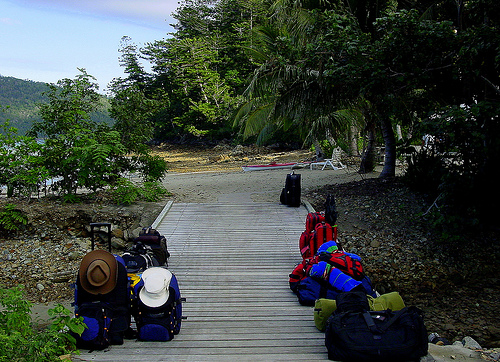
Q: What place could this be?
A: It is a sidewalk.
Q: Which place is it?
A: It is a sidewalk.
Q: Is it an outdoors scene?
A: Yes, it is outdoors.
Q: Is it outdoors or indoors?
A: It is outdoors.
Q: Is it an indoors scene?
A: No, it is outdoors.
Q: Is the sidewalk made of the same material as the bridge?
A: Yes, both the sidewalk and the bridge are made of wood.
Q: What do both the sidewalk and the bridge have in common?
A: The material, both the sidewalk and the bridge are wooden.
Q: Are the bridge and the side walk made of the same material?
A: Yes, both the bridge and the side walk are made of wood.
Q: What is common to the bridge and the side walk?
A: The material, both the bridge and the side walk are wooden.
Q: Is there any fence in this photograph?
A: No, there are no fences.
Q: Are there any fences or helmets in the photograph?
A: No, there are no fences or helmets.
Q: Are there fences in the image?
A: No, there are no fences.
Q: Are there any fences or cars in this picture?
A: No, there are no fences or cars.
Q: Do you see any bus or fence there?
A: No, there are no fences or buses.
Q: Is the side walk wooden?
A: Yes, the side walk is wooden.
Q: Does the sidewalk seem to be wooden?
A: Yes, the sidewalk is wooden.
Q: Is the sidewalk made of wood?
A: Yes, the sidewalk is made of wood.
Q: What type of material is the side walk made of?
A: The side walk is made of wood.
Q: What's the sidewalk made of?
A: The side walk is made of wood.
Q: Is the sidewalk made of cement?
A: No, the sidewalk is made of wood.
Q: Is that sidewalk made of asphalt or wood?
A: The sidewalk is made of wood.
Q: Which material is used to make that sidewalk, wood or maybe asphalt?
A: The sidewalk is made of wood.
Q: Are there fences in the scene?
A: No, there are no fences.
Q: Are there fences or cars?
A: No, there are no fences or cars.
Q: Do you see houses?
A: No, there are no houses.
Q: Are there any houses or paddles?
A: No, there are no houses or paddles.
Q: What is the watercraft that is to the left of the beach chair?
A: The watercraft is a canoe.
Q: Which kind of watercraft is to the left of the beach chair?
A: The watercraft is a canoe.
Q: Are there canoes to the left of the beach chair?
A: Yes, there is a canoe to the left of the beach chair.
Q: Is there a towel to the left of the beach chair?
A: No, there is a canoe to the left of the beach chair.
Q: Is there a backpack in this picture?
A: Yes, there is a backpack.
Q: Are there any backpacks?
A: Yes, there is a backpack.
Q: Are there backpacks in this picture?
A: Yes, there is a backpack.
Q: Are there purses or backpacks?
A: Yes, there is a backpack.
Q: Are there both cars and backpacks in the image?
A: No, there is a backpack but no cars.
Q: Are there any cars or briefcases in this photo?
A: No, there are no cars or briefcases.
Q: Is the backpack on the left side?
A: Yes, the backpack is on the left of the image.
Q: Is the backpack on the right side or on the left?
A: The backpack is on the left of the image.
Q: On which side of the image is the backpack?
A: The backpack is on the left of the image.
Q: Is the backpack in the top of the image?
A: No, the backpack is in the bottom of the image.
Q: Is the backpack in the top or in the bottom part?
A: The backpack is in the bottom of the image.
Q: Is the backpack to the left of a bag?
A: Yes, the backpack is to the left of a bag.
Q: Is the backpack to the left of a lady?
A: No, the backpack is to the left of a bag.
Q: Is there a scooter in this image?
A: No, there are no scooters.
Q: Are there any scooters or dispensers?
A: No, there are no scooters or dispensers.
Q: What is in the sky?
A: The clouds are in the sky.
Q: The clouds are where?
A: The clouds are in the sky.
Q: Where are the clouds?
A: The clouds are in the sky.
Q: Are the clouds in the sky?
A: Yes, the clouds are in the sky.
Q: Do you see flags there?
A: No, there are no flags.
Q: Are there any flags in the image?
A: No, there are no flags.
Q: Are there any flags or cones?
A: No, there are no flags or cones.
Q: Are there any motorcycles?
A: No, there are no motorcycles.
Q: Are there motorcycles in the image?
A: No, there are no motorcycles.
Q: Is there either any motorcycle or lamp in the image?
A: No, there are no motorcycles or lamps.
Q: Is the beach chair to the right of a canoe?
A: Yes, the beach chair is to the right of a canoe.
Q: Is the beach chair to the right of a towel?
A: No, the beach chair is to the right of a canoe.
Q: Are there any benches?
A: No, there are no benches.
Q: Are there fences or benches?
A: No, there are no benches or fences.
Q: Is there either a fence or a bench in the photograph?
A: No, there are no benches or fences.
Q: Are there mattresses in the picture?
A: No, there are no mattresses.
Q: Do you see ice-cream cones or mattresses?
A: No, there are no mattresses or ice-cream cones.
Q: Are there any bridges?
A: Yes, there is a bridge.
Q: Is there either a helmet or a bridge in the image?
A: Yes, there is a bridge.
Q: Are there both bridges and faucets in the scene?
A: No, there is a bridge but no faucets.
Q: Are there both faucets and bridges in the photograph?
A: No, there is a bridge but no faucets.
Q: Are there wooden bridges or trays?
A: Yes, there is a wood bridge.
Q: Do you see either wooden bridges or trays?
A: Yes, there is a wood bridge.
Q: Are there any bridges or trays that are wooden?
A: Yes, the bridge is wooden.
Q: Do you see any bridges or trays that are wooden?
A: Yes, the bridge is wooden.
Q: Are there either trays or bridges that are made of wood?
A: Yes, the bridge is made of wood.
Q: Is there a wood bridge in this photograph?
A: Yes, there is a wood bridge.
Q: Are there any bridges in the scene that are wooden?
A: Yes, there is a bridge that is wooden.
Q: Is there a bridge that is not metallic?
A: Yes, there is a wooden bridge.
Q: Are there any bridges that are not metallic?
A: Yes, there is a wooden bridge.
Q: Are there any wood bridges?
A: Yes, there is a bridge that is made of wood.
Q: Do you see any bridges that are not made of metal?
A: Yes, there is a bridge that is made of wood.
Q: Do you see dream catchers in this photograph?
A: No, there are no dream catchers.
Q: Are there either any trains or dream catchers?
A: No, there are no dream catchers or trains.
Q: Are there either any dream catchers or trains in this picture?
A: No, there are no dream catchers or trains.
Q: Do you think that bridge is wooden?
A: Yes, the bridge is wooden.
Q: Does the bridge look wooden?
A: Yes, the bridge is wooden.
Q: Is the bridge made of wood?
A: Yes, the bridge is made of wood.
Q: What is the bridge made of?
A: The bridge is made of wood.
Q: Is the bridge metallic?
A: No, the bridge is wooden.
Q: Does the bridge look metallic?
A: No, the bridge is wooden.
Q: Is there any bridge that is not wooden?
A: No, there is a bridge but it is wooden.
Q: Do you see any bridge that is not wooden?
A: No, there is a bridge but it is wooden.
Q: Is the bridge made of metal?
A: No, the bridge is made of wood.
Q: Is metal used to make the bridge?
A: No, the bridge is made of wood.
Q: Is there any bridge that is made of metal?
A: No, there is a bridge but it is made of wood.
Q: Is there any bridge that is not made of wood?
A: No, there is a bridge but it is made of wood.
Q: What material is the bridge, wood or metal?
A: The bridge is made of wood.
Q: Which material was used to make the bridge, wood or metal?
A: The bridge is made of wood.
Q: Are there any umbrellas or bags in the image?
A: Yes, there is a bag.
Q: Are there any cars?
A: No, there are no cars.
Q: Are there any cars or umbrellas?
A: No, there are no cars or umbrellas.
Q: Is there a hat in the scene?
A: Yes, there is a hat.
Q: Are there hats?
A: Yes, there is a hat.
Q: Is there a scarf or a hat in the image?
A: Yes, there is a hat.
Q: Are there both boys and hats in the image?
A: No, there is a hat but no boys.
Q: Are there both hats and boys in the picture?
A: No, there is a hat but no boys.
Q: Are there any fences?
A: No, there are no fences.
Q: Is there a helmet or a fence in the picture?
A: No, there are no fences or helmets.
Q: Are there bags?
A: Yes, there is a bag.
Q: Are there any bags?
A: Yes, there is a bag.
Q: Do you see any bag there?
A: Yes, there is a bag.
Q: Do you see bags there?
A: Yes, there is a bag.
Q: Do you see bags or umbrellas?
A: Yes, there is a bag.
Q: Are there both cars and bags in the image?
A: No, there is a bag but no cars.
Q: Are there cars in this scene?
A: No, there are no cars.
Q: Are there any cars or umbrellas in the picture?
A: No, there are no cars or umbrellas.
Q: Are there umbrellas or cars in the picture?
A: No, there are no cars or umbrellas.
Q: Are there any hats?
A: Yes, there is a hat.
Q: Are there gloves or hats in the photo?
A: Yes, there is a hat.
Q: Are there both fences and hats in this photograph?
A: No, there is a hat but no fences.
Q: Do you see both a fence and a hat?
A: No, there is a hat but no fences.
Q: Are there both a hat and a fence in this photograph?
A: No, there is a hat but no fences.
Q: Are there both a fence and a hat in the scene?
A: No, there is a hat but no fences.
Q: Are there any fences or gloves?
A: No, there are no fences or gloves.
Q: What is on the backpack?
A: The hat is on the backpack.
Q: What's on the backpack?
A: The hat is on the backpack.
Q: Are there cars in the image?
A: No, there are no cars.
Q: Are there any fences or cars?
A: No, there are no cars or fences.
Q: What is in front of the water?
A: The trees are in front of the water.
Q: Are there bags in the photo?
A: Yes, there is a bag.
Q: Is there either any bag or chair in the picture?
A: Yes, there is a bag.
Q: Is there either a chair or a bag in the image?
A: Yes, there is a bag.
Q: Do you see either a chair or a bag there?
A: Yes, there is a bag.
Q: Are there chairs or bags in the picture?
A: Yes, there is a bag.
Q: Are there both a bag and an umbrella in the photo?
A: No, there is a bag but no umbrellas.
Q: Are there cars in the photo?
A: No, there are no cars.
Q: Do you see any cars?
A: No, there are no cars.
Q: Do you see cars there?
A: No, there are no cars.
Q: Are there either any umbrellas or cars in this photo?
A: No, there are no cars or umbrellas.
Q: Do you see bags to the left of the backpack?
A: No, the bag is to the right of the backpack.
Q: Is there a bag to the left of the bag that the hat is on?
A: No, the bag is to the right of the backpack.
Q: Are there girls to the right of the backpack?
A: No, there is a bag to the right of the backpack.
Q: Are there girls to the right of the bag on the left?
A: No, there is a bag to the right of the backpack.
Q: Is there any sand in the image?
A: Yes, there is sand.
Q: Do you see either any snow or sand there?
A: Yes, there is sand.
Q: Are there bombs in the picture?
A: No, there are no bombs.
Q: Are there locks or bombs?
A: No, there are no bombs or locks.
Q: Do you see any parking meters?
A: No, there are no parking meters.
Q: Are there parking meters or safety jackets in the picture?
A: No, there are no parking meters or safety jackets.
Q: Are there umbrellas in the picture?
A: No, there are no umbrellas.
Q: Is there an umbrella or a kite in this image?
A: No, there are no umbrellas or kites.